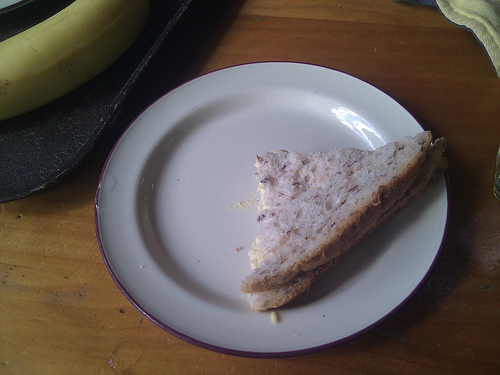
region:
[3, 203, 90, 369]
wooden table with dents in it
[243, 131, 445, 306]
sandwich on a white plate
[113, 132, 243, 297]
white plate with a purple rim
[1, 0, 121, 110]
banana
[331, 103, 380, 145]
reflection on the white plate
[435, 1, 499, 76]
yellow fabric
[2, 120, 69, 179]
black tray on a wooden table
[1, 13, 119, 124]
banana on a black tray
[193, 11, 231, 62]
shadow from the tray on the table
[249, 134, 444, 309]
slices of bread on a plate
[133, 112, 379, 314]
the plate is round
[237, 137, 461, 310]
the sandwich is diagonal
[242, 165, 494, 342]
the sandwich is made of bread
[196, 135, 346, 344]
eggs are on the sandwich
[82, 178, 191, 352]
the plate has a purple rim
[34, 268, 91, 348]
the table is made of wood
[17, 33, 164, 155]
a banana is on the tray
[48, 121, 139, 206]
the tray is black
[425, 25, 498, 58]
the cloth is green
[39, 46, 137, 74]
dark spots are on the banana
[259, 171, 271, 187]
brown speck on bread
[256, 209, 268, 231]
brown speck on bread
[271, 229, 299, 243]
brown speck on bread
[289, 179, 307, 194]
brown speck on bread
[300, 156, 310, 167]
brown speck on bread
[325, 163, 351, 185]
brown speck on bread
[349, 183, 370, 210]
brown speck on bread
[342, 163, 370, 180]
brown speck on bread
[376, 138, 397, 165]
brown speck on bread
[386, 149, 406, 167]
brown speck on bread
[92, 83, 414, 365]
a plate with a piece of bread on it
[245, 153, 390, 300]
two piece of breading making a sandwhich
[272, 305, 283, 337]
the crumb of a piece of bread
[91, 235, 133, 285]
the blue rim of a china plate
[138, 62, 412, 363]
a large white china plate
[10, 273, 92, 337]
a brown wooden table top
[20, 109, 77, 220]
a large black fruit bowl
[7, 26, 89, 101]
the yellow peel of a banana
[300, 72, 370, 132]
light reflecting on a plate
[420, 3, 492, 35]
the small edge of a towel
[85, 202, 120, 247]
The plate has a blue trim.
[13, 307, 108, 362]
The table is brown in color.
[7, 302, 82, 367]
The table is made from wood.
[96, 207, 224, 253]
The plate is white.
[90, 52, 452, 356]
The plate is round.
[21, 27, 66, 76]
The banana is yellow.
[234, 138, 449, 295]
The sandwich is shaped as a triangle.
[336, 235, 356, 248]
The bread crust is brown.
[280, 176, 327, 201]
The bread has seeds.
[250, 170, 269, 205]
The egg salad is yellow.